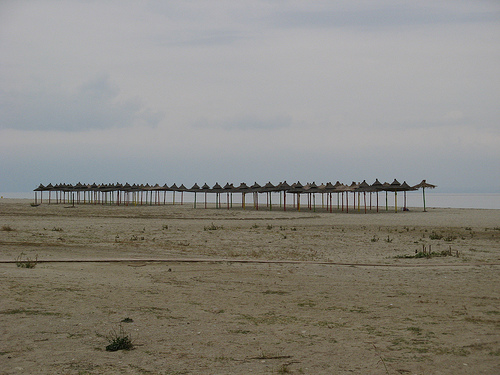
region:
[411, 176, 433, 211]
a thatched beach umbrella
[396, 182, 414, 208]
a thatched beach umbrella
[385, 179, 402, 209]
a thatched beach umbrella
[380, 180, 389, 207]
a thatched beach umbrella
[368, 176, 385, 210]
a thatched beach umbrella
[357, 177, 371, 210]
a thatched beach umbrella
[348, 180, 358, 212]
a thatched beach umbrella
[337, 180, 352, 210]
a thatched beach umbrella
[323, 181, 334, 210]
a thatched beach umbrella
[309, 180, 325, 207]
a thatched beach umbrella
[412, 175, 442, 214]
an umbrella in the sand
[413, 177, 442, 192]
the top of an umbrella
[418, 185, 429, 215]
an umbrella pole on the sand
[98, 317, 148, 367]
a small plant in the sand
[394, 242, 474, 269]
a patch of plants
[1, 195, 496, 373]
a brown sandy expanse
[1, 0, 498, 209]
a cloudy gray sky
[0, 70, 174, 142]
a dark cloud in the sky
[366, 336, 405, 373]
a branch in the sand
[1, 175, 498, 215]
a row of umbrellas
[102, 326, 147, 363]
dead plant on ground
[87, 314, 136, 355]
dead plant on ground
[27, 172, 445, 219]
Row of huts on beach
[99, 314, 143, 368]
Small leafy plant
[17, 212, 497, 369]
Beach is long and brown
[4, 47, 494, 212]
Sky is cloudy and gray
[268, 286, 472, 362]
Small grassy area on sand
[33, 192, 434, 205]
Poles of huts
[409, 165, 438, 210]
Individual hut is brown and short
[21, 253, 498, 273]
Long line in the sand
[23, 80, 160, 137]
Gray cloud in the sky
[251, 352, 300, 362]
Stick in sand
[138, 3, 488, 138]
the cloud is dark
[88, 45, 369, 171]
the cloud is dark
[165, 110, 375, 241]
the cloud is dark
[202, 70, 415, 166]
the cloud is dark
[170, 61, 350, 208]
the cloud is dark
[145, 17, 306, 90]
the cloud is dark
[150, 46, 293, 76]
the cloud is dark